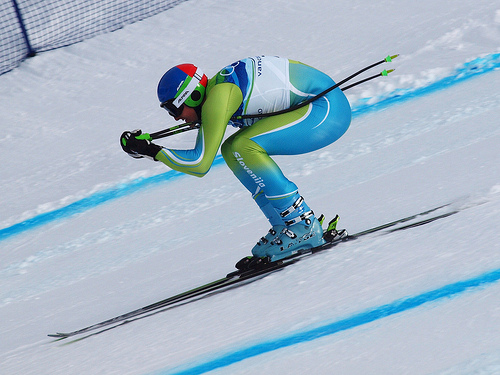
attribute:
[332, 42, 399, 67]
stick — ski pole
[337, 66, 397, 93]
stick — ski pole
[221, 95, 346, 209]
blue pants — green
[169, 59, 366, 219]
costume — blue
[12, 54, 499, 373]
lines — blue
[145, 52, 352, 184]
shirt — green, blue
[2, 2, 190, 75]
fence — blue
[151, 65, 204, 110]
helmet — red, blue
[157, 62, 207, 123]
helmet — blue 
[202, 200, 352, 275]
shoes — blue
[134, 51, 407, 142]
poles — black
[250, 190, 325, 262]
boots — blue, white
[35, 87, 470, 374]
skis — black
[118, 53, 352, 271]
man — skiing competitively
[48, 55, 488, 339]
man — skiing 